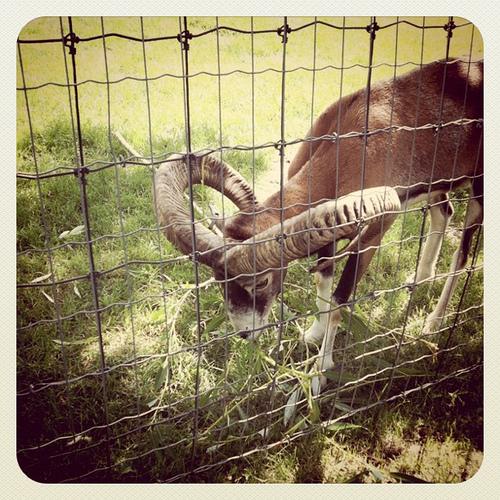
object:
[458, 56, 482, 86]
light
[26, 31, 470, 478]
ground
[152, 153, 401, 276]
curved horns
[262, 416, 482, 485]
light shining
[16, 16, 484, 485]
grass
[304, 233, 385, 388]
legs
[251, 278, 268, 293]
eye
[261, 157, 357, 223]
animal's neck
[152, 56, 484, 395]
animal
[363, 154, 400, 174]
fur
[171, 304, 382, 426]
plant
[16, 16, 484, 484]
fence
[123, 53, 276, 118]
sun